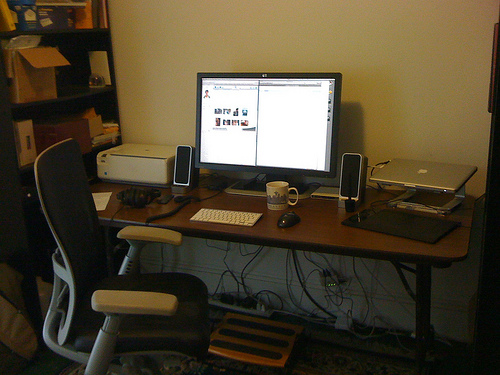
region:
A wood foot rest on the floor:
[206, 307, 311, 369]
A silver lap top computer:
[368, 157, 479, 194]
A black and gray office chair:
[33, 135, 211, 371]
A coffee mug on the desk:
[264, 178, 297, 213]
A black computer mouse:
[277, 209, 302, 227]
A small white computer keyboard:
[190, 206, 262, 226]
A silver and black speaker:
[337, 151, 364, 206]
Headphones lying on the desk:
[114, 185, 161, 208]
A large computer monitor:
[192, 72, 343, 176]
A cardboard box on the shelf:
[0, 46, 71, 101]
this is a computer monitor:
[163, 41, 375, 192]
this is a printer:
[80, 121, 195, 215]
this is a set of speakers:
[143, 131, 410, 205]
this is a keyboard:
[178, 192, 277, 234]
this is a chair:
[8, 96, 245, 373]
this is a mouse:
[279, 204, 311, 241]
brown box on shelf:
[8, 24, 79, 110]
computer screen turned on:
[193, 68, 341, 179]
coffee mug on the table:
[266, 177, 298, 213]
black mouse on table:
[278, 208, 302, 230]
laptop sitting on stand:
[368, 151, 478, 199]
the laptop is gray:
[369, 154, 480, 196]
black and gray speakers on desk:
[167, 139, 366, 207]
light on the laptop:
[439, 184, 449, 194]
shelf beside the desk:
[1, 2, 133, 351]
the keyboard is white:
[187, 207, 264, 229]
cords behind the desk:
[136, 237, 417, 339]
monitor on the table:
[141, 49, 366, 210]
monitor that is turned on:
[163, 73, 363, 190]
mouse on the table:
[261, 199, 316, 239]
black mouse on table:
[259, 199, 307, 241]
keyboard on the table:
[191, 193, 263, 240]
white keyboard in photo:
[178, 198, 265, 248]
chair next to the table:
[7, 126, 231, 371]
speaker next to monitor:
[328, 138, 383, 211]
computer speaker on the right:
[339, 146, 363, 211]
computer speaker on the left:
[164, 140, 197, 202]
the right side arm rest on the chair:
[83, 283, 190, 318]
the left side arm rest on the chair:
[115, 221, 185, 246]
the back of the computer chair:
[22, 140, 91, 368]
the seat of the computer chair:
[71, 267, 221, 357]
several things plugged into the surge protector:
[206, 281, 288, 324]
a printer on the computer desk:
[96, 137, 176, 192]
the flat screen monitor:
[190, 60, 340, 182]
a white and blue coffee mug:
[260, 178, 302, 209]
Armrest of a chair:
[87, 284, 183, 324]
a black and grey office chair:
[29, 132, 211, 374]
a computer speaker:
[172, 140, 196, 188]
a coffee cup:
[265, 179, 299, 213]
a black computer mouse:
[274, 205, 300, 229]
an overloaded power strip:
[206, 287, 277, 318]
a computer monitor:
[195, 68, 338, 195]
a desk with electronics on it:
[71, 67, 478, 372]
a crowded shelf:
[0, 0, 118, 371]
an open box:
[3, 41, 71, 102]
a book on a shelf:
[15, 117, 40, 168]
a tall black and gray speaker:
[340, 148, 367, 205]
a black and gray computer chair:
[30, 133, 212, 374]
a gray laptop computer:
[366, 157, 478, 192]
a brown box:
[1, 43, 72, 103]